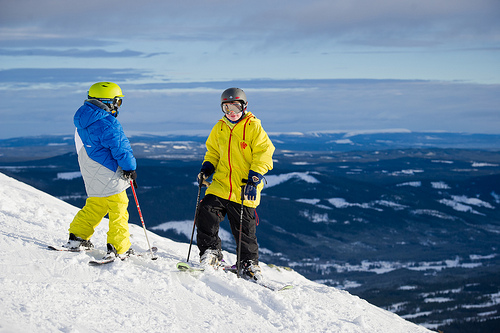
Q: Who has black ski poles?
A: The boy.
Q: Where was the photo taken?
A: Outside somewhere.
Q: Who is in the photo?
A: Two people.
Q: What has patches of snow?
A: The mountains.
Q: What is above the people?
A: The sky.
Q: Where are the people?
A: In the snow.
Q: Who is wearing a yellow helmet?
A: The person.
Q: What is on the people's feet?
A: Skis.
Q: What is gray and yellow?
A: Helmets.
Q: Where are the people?
A: Side of snow covered mountain.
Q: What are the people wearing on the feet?
A: Skis.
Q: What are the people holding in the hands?
A: Ski poles.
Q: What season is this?
A: Winter.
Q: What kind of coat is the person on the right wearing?
A: Yellow coat with red accents.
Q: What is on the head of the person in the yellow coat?
A: Helmet.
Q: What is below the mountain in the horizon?
A: Plains and mountains.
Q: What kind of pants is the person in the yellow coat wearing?
A: Black pants.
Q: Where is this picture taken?
A: Mountain top.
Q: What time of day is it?
A: Daytime.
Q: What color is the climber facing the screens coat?
A: Yellow.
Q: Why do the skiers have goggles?
A: Sunny.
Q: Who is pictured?
A: Climbers.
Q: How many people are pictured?
A: Two.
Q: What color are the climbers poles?
A: Red and black.